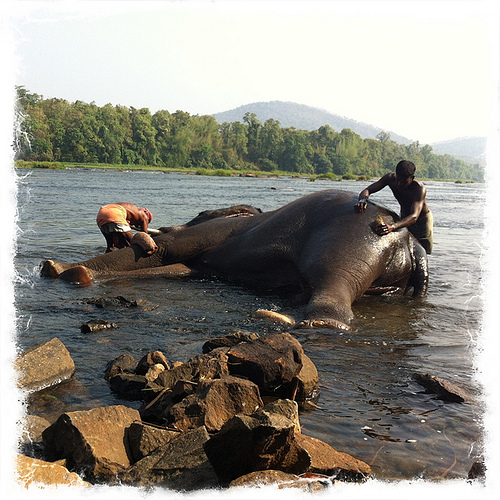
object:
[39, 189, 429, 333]
elephant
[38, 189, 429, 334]
body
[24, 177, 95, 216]
water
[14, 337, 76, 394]
rocks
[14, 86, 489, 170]
landscape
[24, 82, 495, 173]
area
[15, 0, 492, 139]
sky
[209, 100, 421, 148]
hill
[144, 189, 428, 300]
side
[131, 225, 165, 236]
tusk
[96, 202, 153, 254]
man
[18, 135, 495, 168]
shorline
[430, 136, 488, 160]
hill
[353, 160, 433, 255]
man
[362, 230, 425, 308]
back side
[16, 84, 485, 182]
trees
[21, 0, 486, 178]
other side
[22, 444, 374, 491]
river shore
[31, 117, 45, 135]
leaves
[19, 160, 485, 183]
shore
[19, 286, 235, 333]
ripples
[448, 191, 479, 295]
surface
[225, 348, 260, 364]
spots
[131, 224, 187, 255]
trunk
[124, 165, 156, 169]
grass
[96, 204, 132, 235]
clothing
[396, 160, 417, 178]
hair